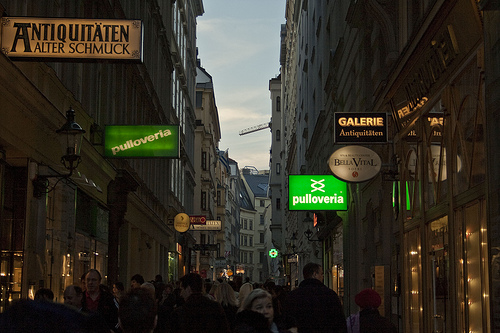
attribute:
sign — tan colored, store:
[166, 207, 196, 232]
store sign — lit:
[295, 175, 355, 218]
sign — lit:
[333, 110, 391, 146]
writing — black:
[14, 21, 130, 53]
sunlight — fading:
[208, 3, 290, 195]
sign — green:
[98, 122, 180, 159]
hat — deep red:
[354, 287, 381, 308]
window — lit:
[391, 197, 438, 312]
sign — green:
[105, 125, 170, 157]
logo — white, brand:
[285, 167, 353, 214]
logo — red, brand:
[325, 145, 390, 186]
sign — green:
[103, 115, 184, 159]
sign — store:
[2, 21, 141, 63]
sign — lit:
[0, 15, 145, 65]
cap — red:
[351, 283, 384, 309]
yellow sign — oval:
[171, 209, 189, 236]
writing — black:
[30, 39, 136, 59]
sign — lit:
[1, 17, 143, 59]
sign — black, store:
[332, 109, 389, 144]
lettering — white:
[336, 116, 384, 137]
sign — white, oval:
[327, 142, 383, 184]